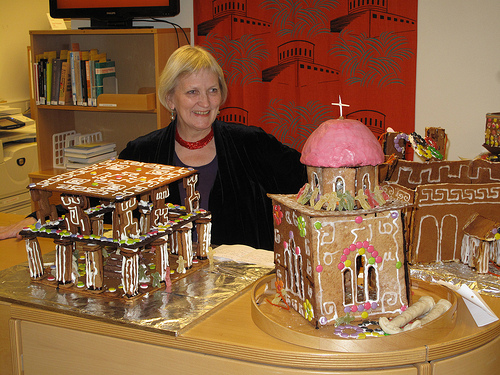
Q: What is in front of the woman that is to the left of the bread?
A: The house is in front of the woman.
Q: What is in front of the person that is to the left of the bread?
A: The house is in front of the woman.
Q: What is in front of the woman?
A: The house is in front of the woman.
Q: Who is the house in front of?
A: The house is in front of the woman.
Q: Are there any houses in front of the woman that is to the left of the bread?
A: Yes, there is a house in front of the woman.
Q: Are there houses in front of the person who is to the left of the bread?
A: Yes, there is a house in front of the woman.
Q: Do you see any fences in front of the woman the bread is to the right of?
A: No, there is a house in front of the woman.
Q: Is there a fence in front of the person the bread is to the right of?
A: No, there is a house in front of the woman.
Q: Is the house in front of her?
A: Yes, the house is in front of the woman.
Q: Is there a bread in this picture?
A: Yes, there is a bread.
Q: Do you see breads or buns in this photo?
A: Yes, there is a bread.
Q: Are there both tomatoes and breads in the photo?
A: No, there is a bread but no tomatoes.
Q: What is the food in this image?
A: The food is a bread.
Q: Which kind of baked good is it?
A: The food is a bread.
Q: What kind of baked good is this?
A: This is a bread.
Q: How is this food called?
A: This is a bread.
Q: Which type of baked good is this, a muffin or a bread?
A: This is a bread.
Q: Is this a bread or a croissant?
A: This is a bread.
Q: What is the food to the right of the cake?
A: The food is a bread.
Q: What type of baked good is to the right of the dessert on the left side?
A: The food is a bread.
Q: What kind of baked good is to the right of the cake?
A: The food is a bread.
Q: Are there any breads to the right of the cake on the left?
A: Yes, there is a bread to the right of the cake.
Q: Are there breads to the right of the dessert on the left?
A: Yes, there is a bread to the right of the cake.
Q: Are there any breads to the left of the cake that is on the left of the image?
A: No, the bread is to the right of the cake.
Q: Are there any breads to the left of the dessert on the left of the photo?
A: No, the bread is to the right of the cake.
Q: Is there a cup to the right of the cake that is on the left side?
A: No, there is a bread to the right of the cake.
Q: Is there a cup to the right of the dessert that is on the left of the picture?
A: No, there is a bread to the right of the cake.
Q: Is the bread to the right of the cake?
A: Yes, the bread is to the right of the cake.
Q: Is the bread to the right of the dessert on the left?
A: Yes, the bread is to the right of the cake.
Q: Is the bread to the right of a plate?
A: No, the bread is to the right of the cake.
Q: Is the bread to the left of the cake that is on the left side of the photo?
A: No, the bread is to the right of the cake.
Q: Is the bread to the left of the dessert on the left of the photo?
A: No, the bread is to the right of the cake.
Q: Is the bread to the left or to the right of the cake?
A: The bread is to the right of the cake.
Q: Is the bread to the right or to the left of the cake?
A: The bread is to the right of the cake.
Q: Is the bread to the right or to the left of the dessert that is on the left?
A: The bread is to the right of the cake.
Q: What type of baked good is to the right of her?
A: The food is a bread.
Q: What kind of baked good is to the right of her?
A: The food is a bread.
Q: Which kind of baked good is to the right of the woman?
A: The food is a bread.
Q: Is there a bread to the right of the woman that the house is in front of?
A: Yes, there is a bread to the right of the woman.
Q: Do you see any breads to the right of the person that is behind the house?
A: Yes, there is a bread to the right of the woman.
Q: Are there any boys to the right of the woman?
A: No, there is a bread to the right of the woman.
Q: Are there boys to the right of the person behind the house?
A: No, there is a bread to the right of the woman.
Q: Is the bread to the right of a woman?
A: Yes, the bread is to the right of a woman.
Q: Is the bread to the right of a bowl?
A: No, the bread is to the right of a woman.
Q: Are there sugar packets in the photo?
A: No, there are no sugar packets.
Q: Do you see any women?
A: Yes, there is a woman.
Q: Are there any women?
A: Yes, there is a woman.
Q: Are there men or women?
A: Yes, there is a woman.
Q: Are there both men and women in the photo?
A: No, there is a woman but no men.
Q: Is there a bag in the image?
A: No, there are no bags.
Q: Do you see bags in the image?
A: No, there are no bags.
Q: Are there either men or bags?
A: No, there are no bags or men.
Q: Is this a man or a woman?
A: This is a woman.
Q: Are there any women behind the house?
A: Yes, there is a woman behind the house.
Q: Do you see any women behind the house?
A: Yes, there is a woman behind the house.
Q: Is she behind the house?
A: Yes, the woman is behind the house.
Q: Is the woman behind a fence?
A: No, the woman is behind the house.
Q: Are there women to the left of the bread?
A: Yes, there is a woman to the left of the bread.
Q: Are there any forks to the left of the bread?
A: No, there is a woman to the left of the bread.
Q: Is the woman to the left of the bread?
A: Yes, the woman is to the left of the bread.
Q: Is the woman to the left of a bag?
A: No, the woman is to the left of the bread.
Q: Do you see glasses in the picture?
A: No, there are no glasses.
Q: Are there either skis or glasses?
A: No, there are no glasses or skis.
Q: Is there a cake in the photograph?
A: Yes, there is a cake.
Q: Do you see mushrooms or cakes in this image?
A: Yes, there is a cake.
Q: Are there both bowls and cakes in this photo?
A: No, there is a cake but no bowls.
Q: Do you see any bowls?
A: No, there are no bowls.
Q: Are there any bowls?
A: No, there are no bowls.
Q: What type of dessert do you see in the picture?
A: The dessert is a cake.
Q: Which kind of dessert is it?
A: The dessert is a cake.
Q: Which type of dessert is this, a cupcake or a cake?
A: That is a cake.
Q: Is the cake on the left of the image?
A: Yes, the cake is on the left of the image.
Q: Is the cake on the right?
A: No, the cake is on the left of the image.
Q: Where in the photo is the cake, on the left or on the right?
A: The cake is on the left of the image.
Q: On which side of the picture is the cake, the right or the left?
A: The cake is on the left of the image.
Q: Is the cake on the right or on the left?
A: The cake is on the left of the image.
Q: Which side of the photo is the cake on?
A: The cake is on the left of the image.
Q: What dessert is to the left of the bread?
A: The dessert is a cake.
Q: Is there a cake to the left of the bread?
A: Yes, there is a cake to the left of the bread.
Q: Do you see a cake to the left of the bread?
A: Yes, there is a cake to the left of the bread.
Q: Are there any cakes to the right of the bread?
A: No, the cake is to the left of the bread.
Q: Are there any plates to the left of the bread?
A: No, there is a cake to the left of the bread.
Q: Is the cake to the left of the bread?
A: Yes, the cake is to the left of the bread.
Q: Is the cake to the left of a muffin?
A: No, the cake is to the left of the bread.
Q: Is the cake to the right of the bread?
A: No, the cake is to the left of the bread.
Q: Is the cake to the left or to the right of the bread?
A: The cake is to the left of the bread.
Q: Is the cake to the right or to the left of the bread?
A: The cake is to the left of the bread.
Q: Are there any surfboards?
A: No, there are no surfboards.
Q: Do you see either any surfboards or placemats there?
A: No, there are no surfboards or placemats.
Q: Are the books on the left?
A: Yes, the books are on the left of the image.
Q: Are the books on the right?
A: No, the books are on the left of the image.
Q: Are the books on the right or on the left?
A: The books are on the left of the image.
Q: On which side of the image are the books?
A: The books are on the left of the image.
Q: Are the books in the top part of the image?
A: Yes, the books are in the top of the image.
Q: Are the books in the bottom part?
A: No, the books are in the top of the image.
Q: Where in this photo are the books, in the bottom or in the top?
A: The books are in the top of the image.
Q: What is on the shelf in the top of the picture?
A: The books are on the shelf.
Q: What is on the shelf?
A: The books are on the shelf.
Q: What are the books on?
A: The books are on the shelf.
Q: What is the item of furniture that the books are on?
A: The piece of furniture is a shelf.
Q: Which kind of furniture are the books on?
A: The books are on the shelf.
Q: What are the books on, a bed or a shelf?
A: The books are on a shelf.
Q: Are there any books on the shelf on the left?
A: Yes, there are books on the shelf.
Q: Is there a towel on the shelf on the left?
A: No, there are books on the shelf.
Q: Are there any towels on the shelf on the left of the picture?
A: No, there are books on the shelf.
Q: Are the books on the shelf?
A: Yes, the books are on the shelf.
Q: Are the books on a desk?
A: No, the books are on the shelf.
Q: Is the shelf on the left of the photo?
A: Yes, the shelf is on the left of the image.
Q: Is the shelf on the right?
A: No, the shelf is on the left of the image.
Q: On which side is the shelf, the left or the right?
A: The shelf is on the left of the image.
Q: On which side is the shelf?
A: The shelf is on the left of the image.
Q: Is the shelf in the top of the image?
A: Yes, the shelf is in the top of the image.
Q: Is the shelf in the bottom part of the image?
A: No, the shelf is in the top of the image.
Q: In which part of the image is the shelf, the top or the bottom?
A: The shelf is in the top of the image.